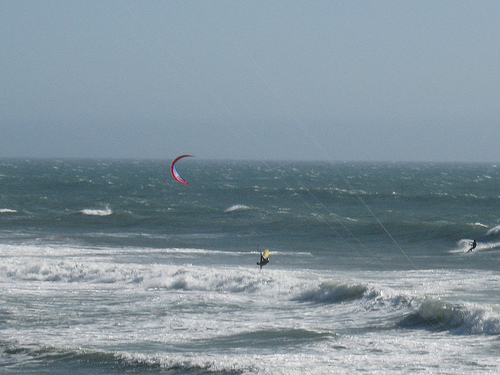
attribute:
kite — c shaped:
[170, 165, 187, 187]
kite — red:
[139, 121, 217, 199]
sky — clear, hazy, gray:
[0, 0, 498, 169]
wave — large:
[296, 259, 423, 324]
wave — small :
[1, 259, 498, 334]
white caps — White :
[35, 151, 148, 202]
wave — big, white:
[282, 267, 454, 359]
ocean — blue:
[32, 160, 467, 352]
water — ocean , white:
[0, 158, 498, 373]